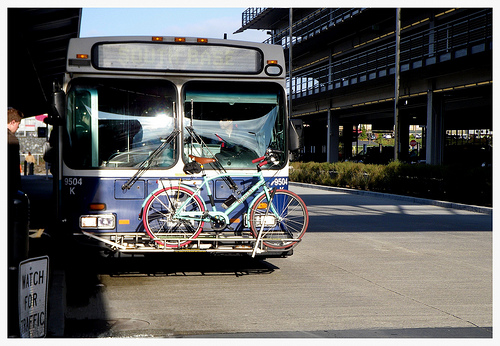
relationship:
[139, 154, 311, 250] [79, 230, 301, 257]
bike on carrier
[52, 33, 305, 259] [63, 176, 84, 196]
bus has numbers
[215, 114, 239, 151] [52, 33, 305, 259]
driver in bus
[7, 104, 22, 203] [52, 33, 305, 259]
man by bus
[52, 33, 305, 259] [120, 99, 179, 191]
bus has wiper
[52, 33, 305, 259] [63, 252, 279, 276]
bus has shadow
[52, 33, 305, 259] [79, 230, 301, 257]
bus has carrier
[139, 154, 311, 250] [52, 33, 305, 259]
bike on bus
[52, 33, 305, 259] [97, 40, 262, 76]
bus displayed destination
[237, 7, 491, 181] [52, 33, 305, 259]
building next to bus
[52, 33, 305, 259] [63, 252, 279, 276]
bus has a shadow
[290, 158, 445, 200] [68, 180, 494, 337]
shrub next to street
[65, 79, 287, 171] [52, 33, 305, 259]
windshield on bus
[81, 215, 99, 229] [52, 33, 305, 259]
light on bus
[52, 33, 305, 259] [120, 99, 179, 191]
bus has a wiper